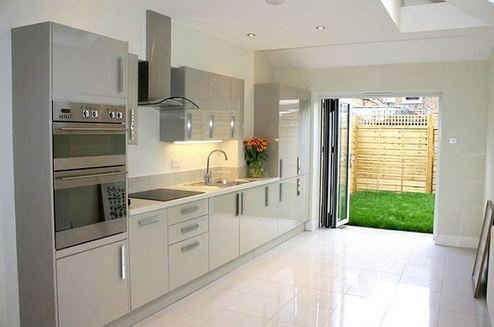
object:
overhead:
[139, 96, 193, 112]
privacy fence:
[344, 110, 439, 203]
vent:
[140, 8, 199, 109]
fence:
[350, 116, 438, 195]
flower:
[258, 145, 263, 151]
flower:
[241, 134, 249, 145]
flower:
[252, 137, 274, 151]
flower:
[257, 138, 265, 142]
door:
[324, 95, 436, 236]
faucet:
[203, 145, 231, 192]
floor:
[277, 242, 457, 294]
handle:
[53, 169, 131, 181]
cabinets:
[51, 27, 491, 321]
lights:
[246, 30, 255, 38]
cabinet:
[488, 229, 492, 306]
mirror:
[471, 200, 492, 294]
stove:
[50, 97, 135, 244]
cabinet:
[208, 182, 264, 265]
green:
[373, 201, 402, 217]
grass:
[357, 190, 426, 225]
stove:
[136, 186, 206, 204]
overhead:
[141, 7, 176, 101]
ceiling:
[1, 2, 493, 71]